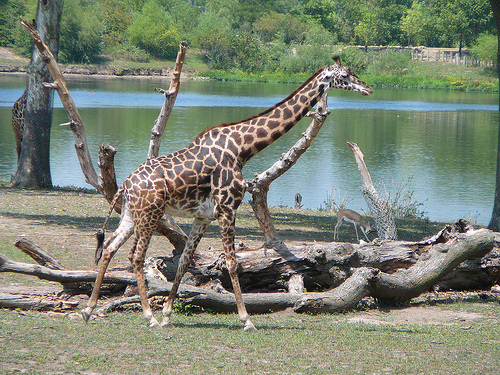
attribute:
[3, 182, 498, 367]
ground — green, brown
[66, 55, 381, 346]
animal — white, brown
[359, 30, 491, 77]
bridge — wooden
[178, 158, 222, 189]
spots — brown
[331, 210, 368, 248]
animal — young, bending down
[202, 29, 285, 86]
tree — distant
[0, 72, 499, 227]
water — light, dark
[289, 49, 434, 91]
flowers — yellow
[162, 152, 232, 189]
spots — brown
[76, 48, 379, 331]
giraffe — walking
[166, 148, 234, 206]
spots — brown